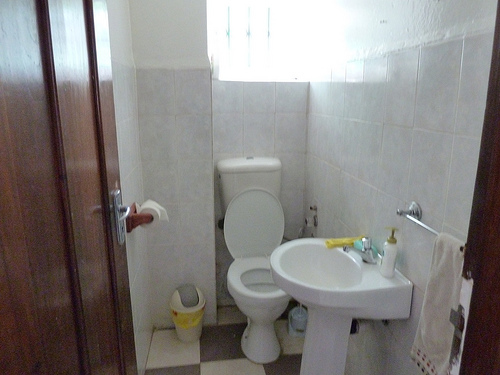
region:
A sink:
[279, 217, 376, 362]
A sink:
[299, 209, 349, 363]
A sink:
[279, 259, 341, 363]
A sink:
[308, 245, 370, 350]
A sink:
[264, 199, 329, 366]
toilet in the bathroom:
[231, 205, 286, 350]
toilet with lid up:
[209, 183, 288, 318]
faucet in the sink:
[329, 236, 380, 274]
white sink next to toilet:
[291, 213, 356, 315]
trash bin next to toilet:
[144, 270, 212, 348]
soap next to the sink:
[372, 221, 409, 279]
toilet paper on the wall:
[130, 186, 182, 253]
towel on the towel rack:
[409, 219, 464, 299]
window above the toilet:
[202, 9, 285, 86]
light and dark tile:
[183, 341, 227, 373]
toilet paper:
[134, 196, 168, 268]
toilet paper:
[131, 178, 191, 282]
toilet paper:
[140, 200, 181, 247]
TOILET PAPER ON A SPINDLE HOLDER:
[126, 197, 178, 232]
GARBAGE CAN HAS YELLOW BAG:
[165, 285, 221, 352]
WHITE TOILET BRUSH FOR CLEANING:
[282, 300, 319, 327]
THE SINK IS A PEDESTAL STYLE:
[268, 210, 410, 367]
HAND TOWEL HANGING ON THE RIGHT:
[396, 223, 447, 373]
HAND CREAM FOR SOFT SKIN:
[373, 225, 402, 289]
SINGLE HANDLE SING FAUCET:
[341, 234, 377, 266]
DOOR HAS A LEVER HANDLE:
[108, 184, 141, 245]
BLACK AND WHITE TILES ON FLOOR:
[156, 330, 310, 372]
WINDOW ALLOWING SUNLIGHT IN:
[173, 1, 330, 83]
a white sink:
[270, 238, 410, 373]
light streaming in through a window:
[203, 0, 375, 82]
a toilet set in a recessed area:
[201, 96, 311, 363]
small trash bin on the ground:
[166, 275, 206, 344]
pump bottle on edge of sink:
[373, 218, 404, 290]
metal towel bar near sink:
[300, 198, 427, 310]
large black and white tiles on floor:
[146, 300, 363, 370]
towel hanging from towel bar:
[408, 217, 464, 372]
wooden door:
[6, 2, 128, 374]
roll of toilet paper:
[126, 192, 169, 237]